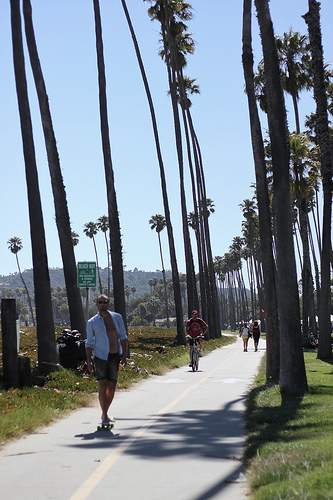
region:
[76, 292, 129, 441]
guy on a skateboard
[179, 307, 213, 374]
guy riding a bike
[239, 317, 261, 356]
a couple walking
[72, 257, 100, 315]
a green sign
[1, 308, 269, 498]
a large road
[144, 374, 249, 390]
go signals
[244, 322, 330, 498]
green grass at the right side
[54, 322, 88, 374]
dumpster between de palm trees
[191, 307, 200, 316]
cap of the guy on the bike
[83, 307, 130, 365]
blue shirt of a guy on the skateboard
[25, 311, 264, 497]
a bycicle path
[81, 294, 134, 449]
a man skateboarding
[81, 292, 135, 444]
a man skateboards on the bike trail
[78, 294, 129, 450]
the man has no shoes on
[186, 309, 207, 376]
a man on a bicycle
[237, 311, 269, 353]
people walk on the bike path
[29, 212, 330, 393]
palm trees on both sides of the bike path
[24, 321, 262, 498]
the bycicle trail has two lanes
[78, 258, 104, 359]
a green street sign is beside the trail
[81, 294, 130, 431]
the skateboarder is wearing shorts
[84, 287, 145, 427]
a person in the road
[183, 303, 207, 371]
a person in the road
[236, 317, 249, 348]
a person in the road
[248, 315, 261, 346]
a person in the road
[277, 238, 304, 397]
a large tree truck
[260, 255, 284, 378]
a large tree truck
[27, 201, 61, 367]
a large tree truck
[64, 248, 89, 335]
a large tree truck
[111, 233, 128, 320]
a large tree truck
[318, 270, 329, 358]
a large tree truck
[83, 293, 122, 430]
man on a skateboard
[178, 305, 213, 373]
person on a bicycle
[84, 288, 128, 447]
man wearing sunglasses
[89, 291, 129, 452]
man with his shirt open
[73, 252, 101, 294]
signpost behind man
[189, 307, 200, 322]
cap on mans head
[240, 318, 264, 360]
two people walking on pavement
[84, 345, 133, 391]
shorts on man on skateboard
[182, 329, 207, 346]
handlebars on the bicycle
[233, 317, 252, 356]
woman wearing yellow shorts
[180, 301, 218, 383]
man with red hat and red shirt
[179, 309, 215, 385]
man riding bicycle on bike path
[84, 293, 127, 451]
man in white shirt riding scooter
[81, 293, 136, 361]
man's white shirt is not buttoned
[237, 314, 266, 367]
two people walking together on path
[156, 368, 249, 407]
arrows let people know where they should walk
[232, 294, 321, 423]
trees, pavement, and green grass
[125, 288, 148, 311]
palm trees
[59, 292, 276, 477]
people enjoying pedestrian only pathway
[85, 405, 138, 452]
man is barefoot on skateboard